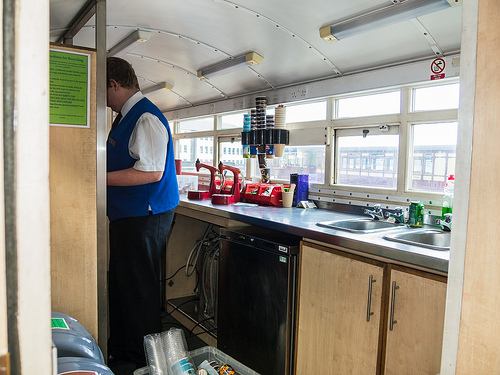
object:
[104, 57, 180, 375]
man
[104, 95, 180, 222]
vest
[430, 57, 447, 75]
white sign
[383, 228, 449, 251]
sink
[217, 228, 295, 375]
refrigerator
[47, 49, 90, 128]
paper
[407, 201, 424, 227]
can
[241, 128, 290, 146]
cup dispenser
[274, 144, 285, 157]
cups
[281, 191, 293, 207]
cup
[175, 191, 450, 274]
counter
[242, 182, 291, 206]
containers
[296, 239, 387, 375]
cabinet doors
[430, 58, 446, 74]
drawing